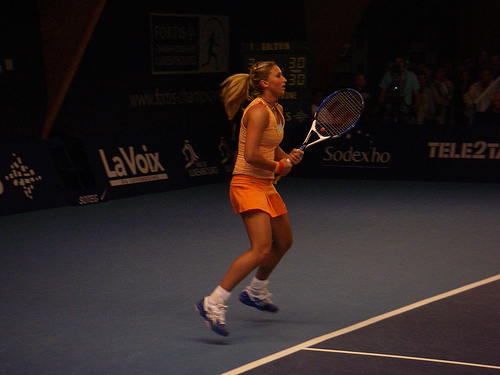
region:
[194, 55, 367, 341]
woman in orange shirt playing tennis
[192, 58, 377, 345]
woman in orange skirt playing tennis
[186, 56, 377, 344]
woman holding blue and white tennis racket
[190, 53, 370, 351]
woman jumping playing tennis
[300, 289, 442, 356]
white lines on tennis court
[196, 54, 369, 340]
woman with pony tail playing tennis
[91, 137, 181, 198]
advertisement in white on black wall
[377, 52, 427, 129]
man in blue shirt watching game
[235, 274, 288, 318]
white shoes with blue trim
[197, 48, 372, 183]
woman holding blue and white racket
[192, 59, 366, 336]
a female tennis player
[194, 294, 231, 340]
a blue and white tennis shoe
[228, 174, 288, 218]
an orange tennis skirt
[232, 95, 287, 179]
an orange tennis top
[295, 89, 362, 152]
a blue and white tennis racket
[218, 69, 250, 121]
a woman's pony tail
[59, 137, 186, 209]
a stadium promotional advertisement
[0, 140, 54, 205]
a stadium promotional advertisement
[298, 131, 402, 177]
a stadium promotional advertisement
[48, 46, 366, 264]
this is a tennis court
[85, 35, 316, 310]
this is a sporting match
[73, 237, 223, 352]
this is a clay court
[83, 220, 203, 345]
the court is light blue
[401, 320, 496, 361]
the court is dark blue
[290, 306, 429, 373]
the lines are white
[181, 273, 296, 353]
the shoes are black and white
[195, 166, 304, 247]
the shorts are orange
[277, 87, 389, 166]
this is a tennis racket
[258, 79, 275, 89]
The left ear of the woman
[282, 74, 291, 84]
The nose of the woman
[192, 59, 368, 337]
female playing tennis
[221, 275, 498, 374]
white stripes on a tennis court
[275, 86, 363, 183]
blue and white tennis racket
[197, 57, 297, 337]
woman wearing an orange tennis outfit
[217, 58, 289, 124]
woman wearing a ponytail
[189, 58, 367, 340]
woman jumping in the air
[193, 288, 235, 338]
Blue and white shoe on a women.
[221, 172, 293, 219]
Orange skirt on a woman.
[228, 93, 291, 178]
Orange shirt on a woman.